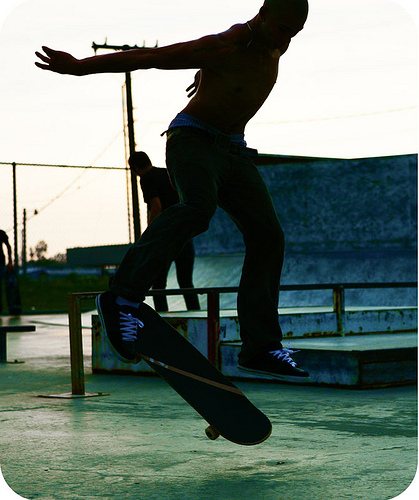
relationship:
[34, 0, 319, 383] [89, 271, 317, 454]
person doing trick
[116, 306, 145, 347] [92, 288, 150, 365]
shoelaces on sneaker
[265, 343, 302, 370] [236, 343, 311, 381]
shoelaces on sneaker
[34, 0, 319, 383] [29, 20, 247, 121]
person has arms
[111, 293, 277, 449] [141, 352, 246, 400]
skateboard has stripe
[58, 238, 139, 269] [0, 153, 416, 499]
building behind skateboard park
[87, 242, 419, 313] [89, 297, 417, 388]
ramp has steps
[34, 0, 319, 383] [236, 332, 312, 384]
person has foot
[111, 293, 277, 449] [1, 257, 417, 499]
skateboard in air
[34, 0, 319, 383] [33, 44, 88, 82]
person has hands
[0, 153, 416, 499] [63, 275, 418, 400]
skateboard park has railing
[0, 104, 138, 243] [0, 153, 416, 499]
powerline behind skateboard park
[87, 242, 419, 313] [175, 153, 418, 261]
skate ramp has wall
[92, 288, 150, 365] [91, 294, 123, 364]
shoes have soles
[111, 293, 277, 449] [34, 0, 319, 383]
skateboard under person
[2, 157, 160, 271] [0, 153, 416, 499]
fence behind skateboard park